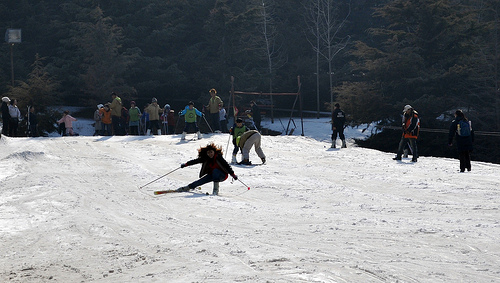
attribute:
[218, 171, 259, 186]
pole — silver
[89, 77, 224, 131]
people — waiting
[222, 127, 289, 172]
man — bending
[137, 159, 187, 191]
ski pole — black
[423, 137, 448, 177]
ground — long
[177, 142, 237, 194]
woman — falling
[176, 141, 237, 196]
person — standing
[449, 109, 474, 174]
person — standing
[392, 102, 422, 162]
person — standing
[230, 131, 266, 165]
person — standing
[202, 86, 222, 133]
person — standing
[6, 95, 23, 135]
man — walking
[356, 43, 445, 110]
leaves — brown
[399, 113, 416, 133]
jacket — orange, black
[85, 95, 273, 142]
people — standing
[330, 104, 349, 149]
man — walking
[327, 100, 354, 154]
man — walking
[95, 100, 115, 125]
jacket — orange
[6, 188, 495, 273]
ski slope — large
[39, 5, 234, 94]
trees — tall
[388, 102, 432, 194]
man — walking, black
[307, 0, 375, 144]
tree — large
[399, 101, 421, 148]
coat — orange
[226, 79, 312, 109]
tripod — brown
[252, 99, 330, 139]
fence — white